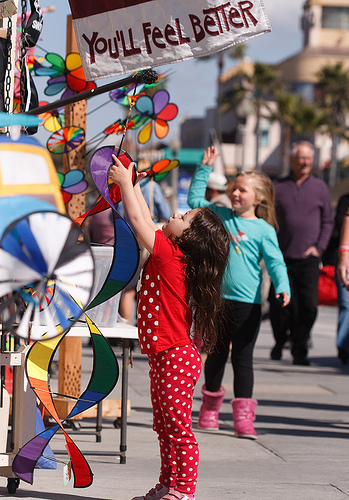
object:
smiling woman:
[184, 145, 291, 439]